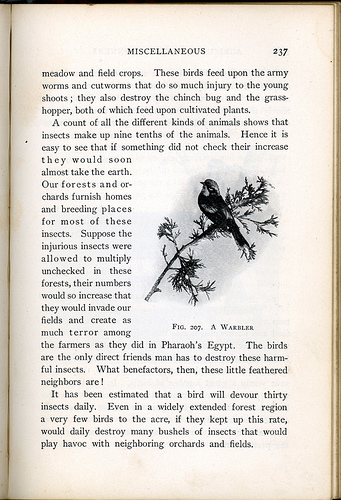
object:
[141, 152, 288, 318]
drawing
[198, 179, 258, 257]
bird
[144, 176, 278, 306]
branch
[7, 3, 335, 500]
page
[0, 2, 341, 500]
book